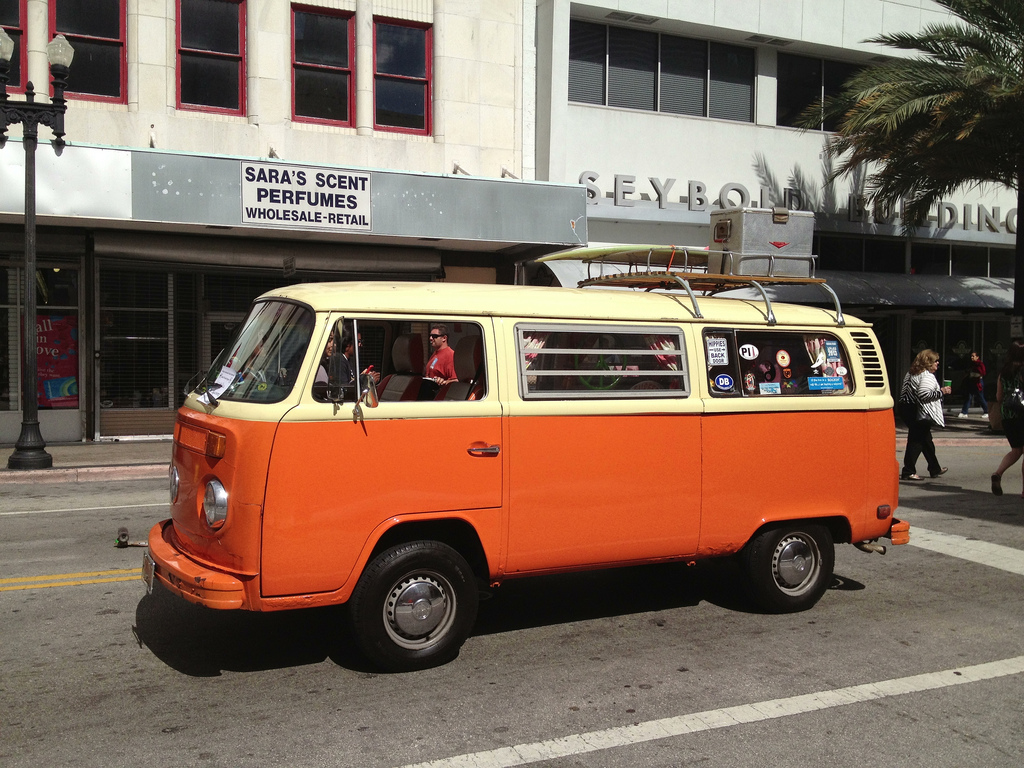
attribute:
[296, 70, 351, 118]
glass — clear, clean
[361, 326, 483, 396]
glass — clean, clear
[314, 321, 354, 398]
glass — clear, clean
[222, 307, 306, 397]
glass — clean, clear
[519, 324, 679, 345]
glass — clear, clean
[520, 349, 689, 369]
glass — clean, clear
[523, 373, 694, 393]
glass — clear, clean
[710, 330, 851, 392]
glass — clear, clean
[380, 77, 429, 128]
glass — clean, clear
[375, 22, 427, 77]
glass — clear, clean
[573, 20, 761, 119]
window — DARK, GRAY, ABOVE, SHADED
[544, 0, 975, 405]
building — WHITE, CONCRETE, RECTANGULAR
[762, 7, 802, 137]
building — CEMENT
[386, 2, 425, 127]
window — DARK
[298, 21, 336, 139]
building — OLD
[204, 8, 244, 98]
window — BLACK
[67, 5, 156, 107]
building — LIMESTONE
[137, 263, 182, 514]
window — TALL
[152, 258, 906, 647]
van — ORANGE